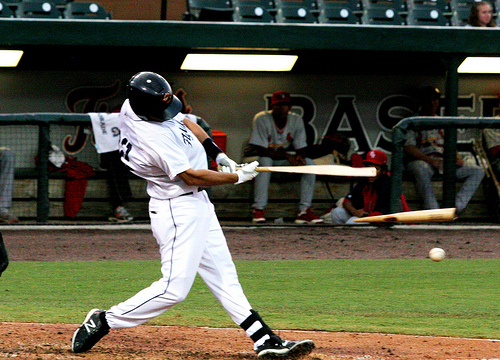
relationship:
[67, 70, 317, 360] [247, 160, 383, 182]
man holding bat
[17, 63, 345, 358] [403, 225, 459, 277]
man hitting ball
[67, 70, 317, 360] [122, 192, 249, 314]
man wearing white pants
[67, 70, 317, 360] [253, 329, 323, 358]
man wearing shoe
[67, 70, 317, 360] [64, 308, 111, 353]
man wearing shoe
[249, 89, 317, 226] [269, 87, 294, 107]
man wearing cap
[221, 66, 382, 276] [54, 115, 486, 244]
man sitting on bench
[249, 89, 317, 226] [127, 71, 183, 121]
man wearing baseball helmet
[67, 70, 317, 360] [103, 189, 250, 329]
man wearing white pants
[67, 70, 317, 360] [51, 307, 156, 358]
man wearing shoes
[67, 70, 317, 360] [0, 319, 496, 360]
man standing in dirt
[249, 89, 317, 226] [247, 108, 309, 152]
man wearing white shirt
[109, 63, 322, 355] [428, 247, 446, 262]
batter swinging at ball